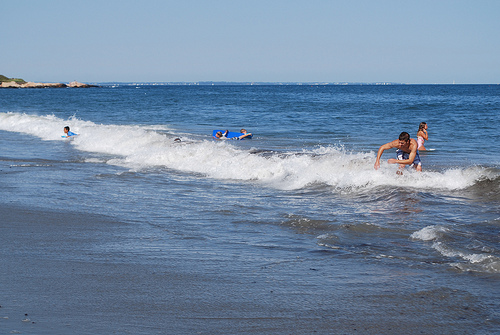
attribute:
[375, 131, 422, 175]
man — leaning over, bent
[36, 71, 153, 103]
land — low, jutting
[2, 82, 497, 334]
water — ocean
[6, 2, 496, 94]
sky — light-blue, clear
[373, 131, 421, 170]
man — young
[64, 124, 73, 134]
person — in blue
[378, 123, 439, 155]
girl — young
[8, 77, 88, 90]
rock — large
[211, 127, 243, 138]
surfboard — blue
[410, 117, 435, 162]
woman — looking, standing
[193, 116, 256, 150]
blue clothing — blue 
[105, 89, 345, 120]
ocean — far-side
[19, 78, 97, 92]
jetty — rock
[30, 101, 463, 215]
wave — crashed